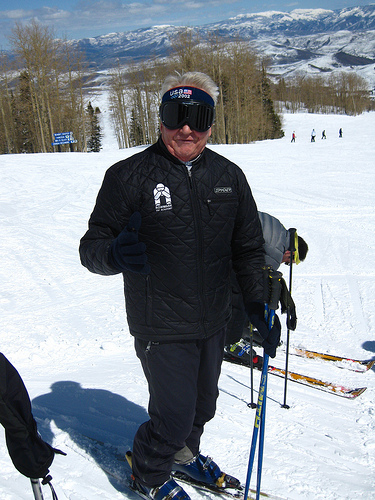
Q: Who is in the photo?
A: A man.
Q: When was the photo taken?
A: Daytime.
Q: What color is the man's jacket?
A: Black.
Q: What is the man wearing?
A: Glasses.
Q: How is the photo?
A: Clear.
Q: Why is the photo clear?
A: Its daytime.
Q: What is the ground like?
A: Snowy.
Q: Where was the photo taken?
A: On the slopes.